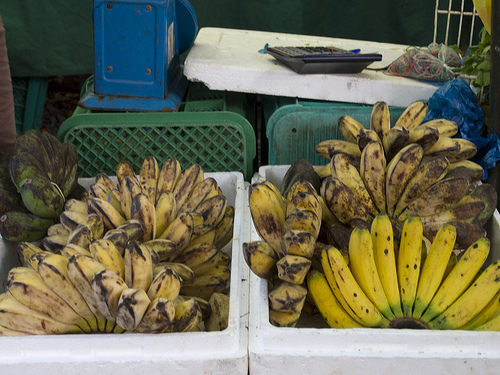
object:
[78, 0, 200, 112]
box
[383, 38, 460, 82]
bands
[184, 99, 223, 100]
lids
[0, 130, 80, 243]
bananas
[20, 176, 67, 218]
banana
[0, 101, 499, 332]
bananas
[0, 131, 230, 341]
bananas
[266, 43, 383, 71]
calculator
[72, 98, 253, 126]
table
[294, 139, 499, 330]
bananas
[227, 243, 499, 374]
tub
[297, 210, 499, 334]
bananas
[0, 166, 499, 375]
tubs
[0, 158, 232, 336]
bananas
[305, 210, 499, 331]
bananas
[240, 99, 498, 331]
fruit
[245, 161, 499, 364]
box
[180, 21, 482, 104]
box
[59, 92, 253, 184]
crate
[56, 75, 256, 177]
basket